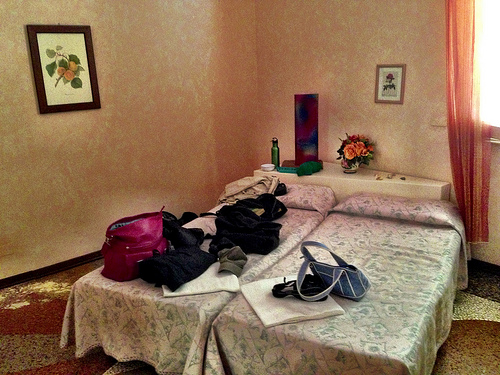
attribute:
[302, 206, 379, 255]
beds — together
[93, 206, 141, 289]
bag — red, open, pink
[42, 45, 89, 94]
flowers — peach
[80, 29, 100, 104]
frame — wood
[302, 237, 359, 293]
bag — blue, denim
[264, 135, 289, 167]
bottle — green, glass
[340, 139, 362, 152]
flowers — orange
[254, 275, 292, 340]
towel — white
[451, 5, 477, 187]
curtains — orange, sheer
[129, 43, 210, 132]
wallpaper — peach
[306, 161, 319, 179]
hat — green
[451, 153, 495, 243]
drapes — long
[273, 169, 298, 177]
item — blue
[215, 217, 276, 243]
bag — black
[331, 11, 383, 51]
wall — decorated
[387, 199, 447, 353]
bed — twin, small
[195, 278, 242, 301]
towel — white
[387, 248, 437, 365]
bedspread — white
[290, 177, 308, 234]
bed — twin